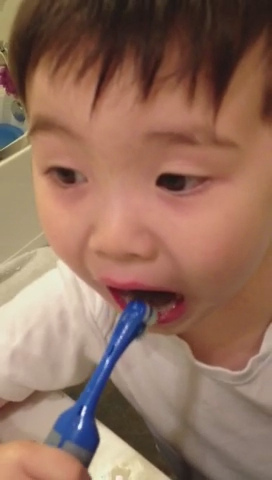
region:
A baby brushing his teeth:
[3, 16, 268, 385]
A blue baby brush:
[45, 301, 205, 478]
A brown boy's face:
[20, 138, 265, 327]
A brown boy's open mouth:
[89, 268, 207, 332]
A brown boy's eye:
[153, 148, 213, 196]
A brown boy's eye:
[44, 163, 80, 187]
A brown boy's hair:
[26, 22, 270, 112]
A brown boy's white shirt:
[37, 290, 270, 448]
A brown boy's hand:
[0, 443, 79, 478]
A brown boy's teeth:
[151, 301, 179, 314]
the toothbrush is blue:
[41, 292, 149, 452]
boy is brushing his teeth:
[15, 139, 212, 421]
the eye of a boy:
[24, 140, 128, 209]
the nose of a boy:
[87, 208, 167, 260]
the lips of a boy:
[93, 274, 215, 345]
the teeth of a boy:
[101, 281, 214, 343]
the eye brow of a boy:
[130, 102, 236, 165]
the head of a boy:
[34, 123, 259, 318]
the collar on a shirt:
[125, 319, 255, 446]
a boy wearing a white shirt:
[21, 200, 270, 408]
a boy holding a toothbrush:
[18, 182, 233, 472]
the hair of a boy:
[21, 13, 258, 114]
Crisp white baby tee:
[157, 377, 254, 439]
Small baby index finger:
[26, 450, 60, 472]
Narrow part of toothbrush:
[86, 356, 109, 399]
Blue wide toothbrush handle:
[47, 422, 99, 444]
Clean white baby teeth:
[158, 302, 172, 311]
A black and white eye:
[147, 160, 223, 202]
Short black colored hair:
[86, 26, 229, 77]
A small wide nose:
[73, 222, 178, 264]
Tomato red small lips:
[105, 277, 173, 296]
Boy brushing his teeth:
[86, 260, 251, 362]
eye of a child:
[39, 148, 229, 209]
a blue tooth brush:
[32, 273, 162, 477]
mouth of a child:
[99, 272, 188, 329]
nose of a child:
[83, 206, 166, 269]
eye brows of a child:
[153, 109, 239, 156]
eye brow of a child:
[21, 114, 105, 158]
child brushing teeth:
[7, 100, 264, 422]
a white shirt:
[1, 243, 269, 466]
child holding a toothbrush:
[46, 272, 165, 479]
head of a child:
[4, 7, 270, 337]